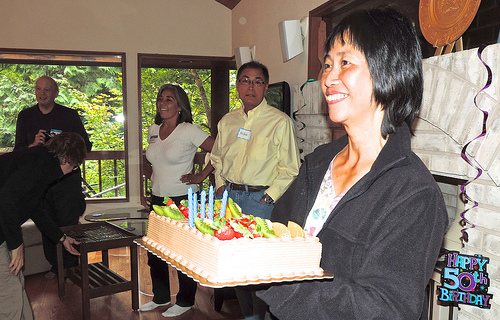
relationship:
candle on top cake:
[218, 188, 230, 226] [141, 184, 325, 284]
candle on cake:
[191, 187, 201, 223] [141, 184, 325, 284]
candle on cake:
[181, 185, 196, 225] [119, 165, 351, 311]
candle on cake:
[208, 179, 217, 223] [145, 201, 320, 281]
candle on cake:
[218, 181, 229, 225] [145, 201, 320, 281]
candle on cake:
[192, 188, 200, 219] [145, 201, 320, 281]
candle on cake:
[192, 185, 196, 225] [145, 201, 320, 281]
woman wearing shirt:
[137, 80, 209, 190] [147, 120, 210, 203]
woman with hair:
[249, 1, 460, 316] [321, 12, 431, 135]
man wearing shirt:
[209, 60, 302, 318] [210, 96, 305, 198]